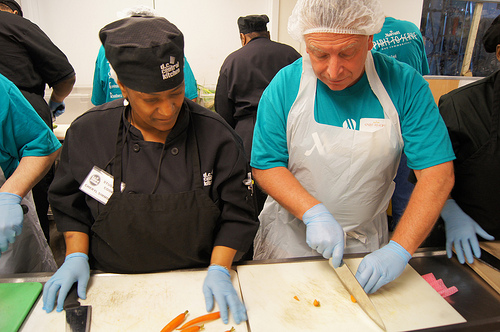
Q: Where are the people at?
A: Kitchen.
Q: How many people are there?
A: Eight.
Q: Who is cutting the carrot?
A: Man.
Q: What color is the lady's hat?
A: Black.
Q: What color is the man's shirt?
A: Blue.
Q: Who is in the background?
A: People.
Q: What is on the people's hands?
A: Gloves.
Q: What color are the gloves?
A: Blue.